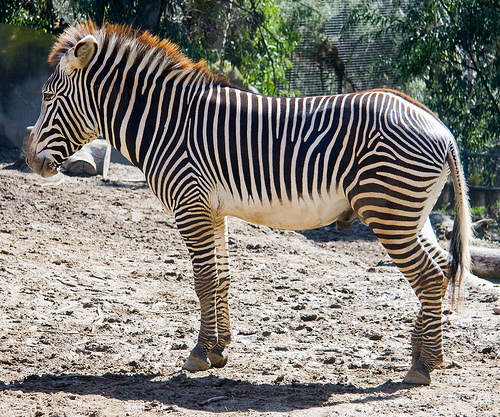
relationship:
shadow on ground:
[3, 363, 426, 409] [17, 364, 496, 414]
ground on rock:
[361, 170, 386, 211] [11, 77, 46, 128]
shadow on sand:
[3, 375, 425, 409] [0, 170, 498, 415]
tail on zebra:
[444, 142, 479, 318] [22, 13, 476, 392]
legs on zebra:
[167, 202, 239, 378] [22, 13, 476, 392]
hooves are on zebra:
[178, 334, 227, 374] [53, 37, 488, 371]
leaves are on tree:
[235, 7, 294, 90] [232, 5, 294, 96]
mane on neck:
[38, 17, 228, 85] [84, 40, 189, 186]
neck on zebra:
[84, 40, 189, 186] [22, 13, 476, 392]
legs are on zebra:
[167, 202, 239, 378] [22, 13, 476, 392]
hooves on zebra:
[178, 354, 214, 373] [22, 13, 476, 392]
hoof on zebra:
[406, 356, 433, 384] [22, 13, 476, 392]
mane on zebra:
[38, 17, 228, 85] [22, 13, 476, 392]